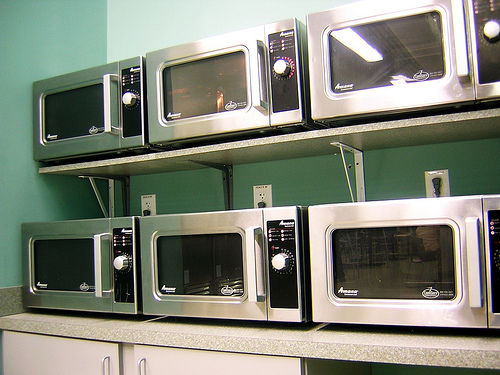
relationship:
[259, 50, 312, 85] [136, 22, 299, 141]
red numbers on oven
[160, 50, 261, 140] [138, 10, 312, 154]
light in oven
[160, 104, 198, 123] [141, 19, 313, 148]
white letters on oven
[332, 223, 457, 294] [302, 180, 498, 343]
reflection in oven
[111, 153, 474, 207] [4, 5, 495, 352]
cords plugged into wall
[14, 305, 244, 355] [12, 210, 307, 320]
counter top with microwave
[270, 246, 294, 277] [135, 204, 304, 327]
knob on microwave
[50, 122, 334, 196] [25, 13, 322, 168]
shelf with microwave ovens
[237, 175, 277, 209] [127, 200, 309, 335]
electrical outlet behind microwave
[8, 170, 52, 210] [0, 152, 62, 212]
green paint on wall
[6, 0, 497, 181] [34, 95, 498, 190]
microwaves on shelf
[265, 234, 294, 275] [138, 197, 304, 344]
silver knob on microwave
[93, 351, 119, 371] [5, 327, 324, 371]
handle on cabinet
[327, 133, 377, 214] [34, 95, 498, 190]
latches under shelf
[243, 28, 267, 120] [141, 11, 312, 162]
door handle of microwave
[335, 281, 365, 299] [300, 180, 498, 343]
white writing on microwave